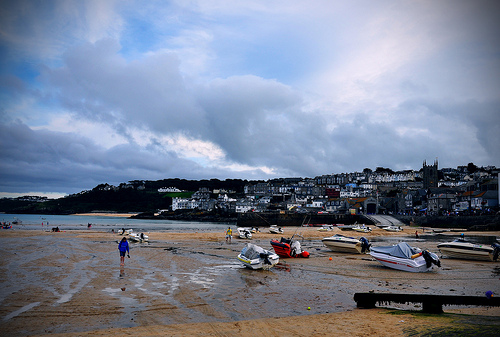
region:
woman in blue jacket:
[113, 239, 136, 263]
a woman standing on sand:
[116, 234, 133, 271]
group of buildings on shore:
[163, 168, 496, 215]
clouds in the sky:
[11, 8, 489, 174]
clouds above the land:
[3, 1, 487, 166]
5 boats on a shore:
[243, 233, 495, 283]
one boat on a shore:
[367, 244, 446, 274]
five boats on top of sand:
[228, 233, 498, 272]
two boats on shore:
[233, 232, 313, 272]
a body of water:
[16, 208, 201, 232]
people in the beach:
[6, 208, 254, 312]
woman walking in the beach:
[110, 234, 138, 276]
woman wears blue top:
[113, 232, 137, 272]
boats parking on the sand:
[234, 216, 498, 294]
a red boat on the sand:
[261, 228, 325, 265]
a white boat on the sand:
[359, 232, 444, 280]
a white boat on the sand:
[311, 226, 373, 251]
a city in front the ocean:
[27, 156, 485, 228]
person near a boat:
[219, 214, 256, 246]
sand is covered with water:
[3, 211, 450, 334]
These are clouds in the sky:
[63, 70, 205, 192]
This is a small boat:
[228, 216, 303, 325]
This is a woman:
[106, 248, 153, 267]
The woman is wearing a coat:
[81, 230, 139, 277]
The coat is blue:
[100, 231, 140, 281]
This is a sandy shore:
[92, 268, 194, 325]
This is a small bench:
[333, 285, 471, 331]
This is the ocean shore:
[47, 208, 172, 269]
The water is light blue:
[21, 213, 178, 277]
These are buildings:
[236, 185, 417, 297]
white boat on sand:
[364, 235, 445, 273]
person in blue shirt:
[115, 233, 134, 273]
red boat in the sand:
[267, 233, 315, 260]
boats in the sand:
[240, 231, 442, 284]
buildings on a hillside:
[172, 166, 432, 218]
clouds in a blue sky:
[33, 56, 269, 147]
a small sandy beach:
[60, 199, 149, 221]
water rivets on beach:
[147, 252, 218, 324]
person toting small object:
[113, 234, 137, 274]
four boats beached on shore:
[235, 231, 445, 281]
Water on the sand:
[124, 292, 183, 318]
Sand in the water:
[119, 297, 151, 316]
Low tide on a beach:
[19, 254, 87, 294]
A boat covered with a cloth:
[375, 243, 410, 252]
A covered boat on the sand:
[371, 246, 427, 271]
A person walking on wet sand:
[116, 235, 131, 268]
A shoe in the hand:
[127, 253, 130, 259]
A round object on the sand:
[327, 254, 332, 262]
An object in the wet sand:
[306, 304, 311, 311]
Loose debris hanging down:
[380, 299, 390, 304]